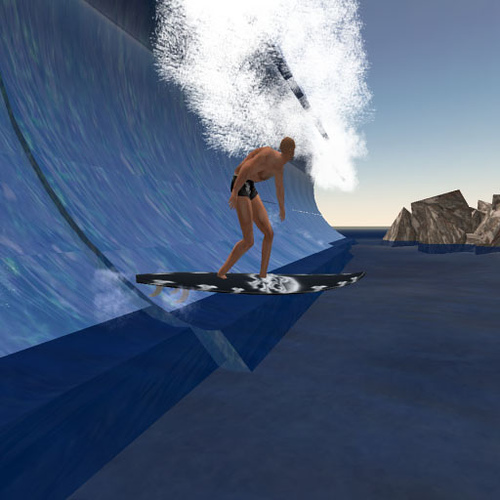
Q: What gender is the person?
A: Male.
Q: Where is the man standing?
A: On the surfboard.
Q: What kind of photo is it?
A: Computer generated photo.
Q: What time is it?
A: Afternoon.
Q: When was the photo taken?
A: During the daytime.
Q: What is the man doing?
A: Surfing.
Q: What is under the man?
A: A board.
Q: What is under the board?
A: Water.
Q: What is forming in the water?
A: A wave.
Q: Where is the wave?
A: In water.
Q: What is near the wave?
A: Rocks.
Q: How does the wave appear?
A: Artificial.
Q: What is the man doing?
A: Virtual surfing.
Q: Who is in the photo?
A: A surfer.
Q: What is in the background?
A: Rocks.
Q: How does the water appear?
A: Calm.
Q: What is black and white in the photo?
A: Surfboard.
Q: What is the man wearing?
A: Swimsuit.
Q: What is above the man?
A: Waves.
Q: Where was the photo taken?
A: By virtual ocean.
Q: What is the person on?
A: Surfboard.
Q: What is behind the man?
A: Wall.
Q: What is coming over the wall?
A: Water.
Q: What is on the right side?
A: Rocks.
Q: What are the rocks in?
A: Water.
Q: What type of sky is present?
A: Clear.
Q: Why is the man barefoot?
A: Balance.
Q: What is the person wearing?
A: Swimsuit.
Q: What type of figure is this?
A: Avatar.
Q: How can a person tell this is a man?
A: Shirtless.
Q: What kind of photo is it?
A: Computer generated.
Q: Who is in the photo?
A: A man.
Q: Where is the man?
A: Water.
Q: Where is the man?
A: The ocean.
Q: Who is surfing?
A: A man.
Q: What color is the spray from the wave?
A: White.